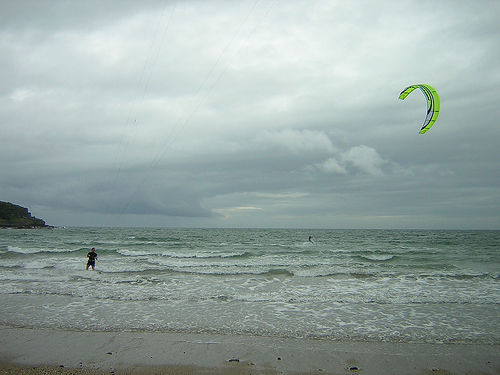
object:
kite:
[397, 84, 441, 135]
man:
[86, 246, 98, 270]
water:
[220, 226, 467, 299]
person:
[307, 233, 315, 243]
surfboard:
[312, 233, 317, 245]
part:
[0, 198, 48, 228]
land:
[0, 200, 52, 227]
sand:
[58, 340, 64, 343]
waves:
[266, 267, 296, 277]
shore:
[0, 328, 500, 372]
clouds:
[0, 0, 499, 124]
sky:
[4, 0, 500, 224]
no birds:
[6, 5, 94, 36]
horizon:
[43, 225, 492, 229]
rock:
[229, 358, 239, 362]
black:
[87, 252, 98, 267]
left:
[13, 114, 69, 206]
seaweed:
[343, 365, 359, 371]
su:
[214, 205, 266, 219]